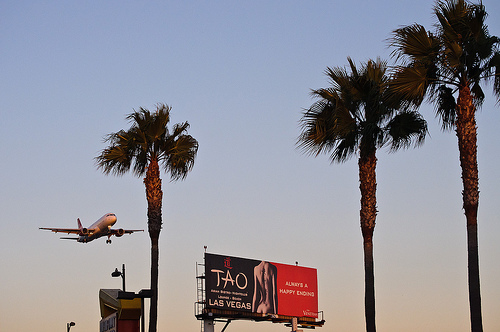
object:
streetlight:
[66, 319, 78, 328]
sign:
[191, 252, 326, 329]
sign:
[100, 315, 115, 327]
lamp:
[109, 267, 122, 284]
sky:
[0, 0, 499, 332]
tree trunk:
[454, 83, 481, 332]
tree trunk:
[355, 140, 376, 330]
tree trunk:
[140, 157, 164, 332]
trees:
[386, 0, 499, 332]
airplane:
[37, 212, 144, 244]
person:
[253, 259, 279, 314]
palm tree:
[97, 99, 198, 331]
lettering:
[211, 267, 252, 288]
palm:
[291, 57, 425, 332]